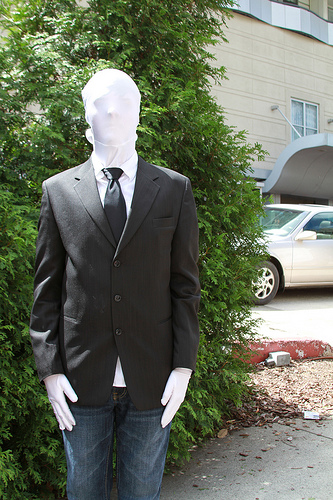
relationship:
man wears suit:
[27, 69, 201, 494] [27, 162, 198, 406]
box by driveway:
[265, 348, 292, 366] [230, 296, 329, 341]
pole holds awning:
[273, 101, 304, 138] [264, 133, 329, 197]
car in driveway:
[223, 203, 331, 298] [230, 296, 329, 341]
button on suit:
[113, 327, 122, 336] [27, 162, 198, 406]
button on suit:
[114, 292, 124, 302] [27, 162, 198, 406]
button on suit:
[112, 256, 122, 269] [27, 162, 198, 406]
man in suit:
[27, 69, 201, 494] [27, 162, 198, 406]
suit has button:
[27, 162, 198, 406] [113, 327, 122, 336]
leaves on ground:
[219, 386, 298, 432] [178, 351, 331, 494]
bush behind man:
[3, 4, 270, 497] [27, 69, 201, 494]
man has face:
[27, 69, 201, 494] [92, 96, 134, 145]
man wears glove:
[27, 69, 201, 494] [158, 363, 192, 427]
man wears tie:
[27, 69, 201, 494] [103, 166, 127, 247]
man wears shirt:
[27, 69, 201, 494] [91, 148, 138, 219]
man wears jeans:
[27, 69, 201, 494] [62, 391, 168, 499]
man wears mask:
[27, 69, 201, 494] [82, 68, 141, 158]